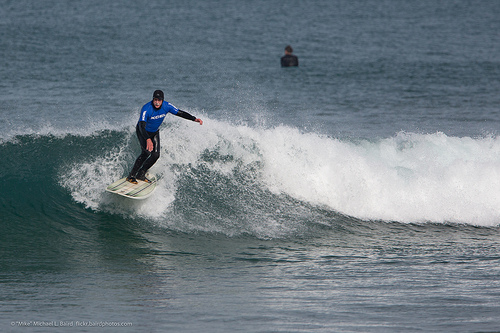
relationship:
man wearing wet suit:
[125, 90, 202, 184] [126, 101, 194, 179]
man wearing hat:
[125, 90, 202, 184] [153, 89, 164, 98]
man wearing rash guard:
[125, 90, 202, 184] [138, 100, 177, 132]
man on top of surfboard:
[125, 90, 202, 184] [104, 174, 162, 200]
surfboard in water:
[104, 174, 162, 200] [1, 0, 497, 328]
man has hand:
[125, 90, 202, 184] [144, 139, 156, 153]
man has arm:
[125, 90, 202, 184] [165, 102, 207, 132]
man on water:
[125, 90, 202, 184] [1, 0, 497, 328]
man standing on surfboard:
[125, 90, 202, 184] [104, 174, 162, 200]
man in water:
[277, 43, 300, 68] [1, 0, 497, 328]